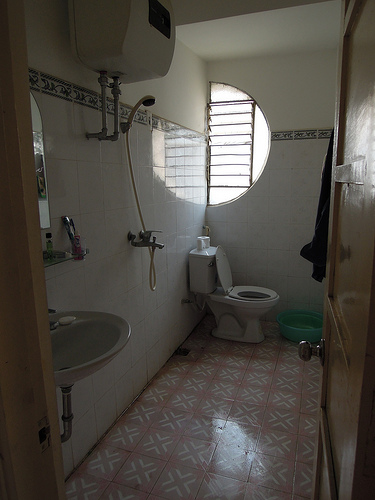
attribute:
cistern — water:
[182, 244, 220, 297]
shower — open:
[76, 5, 227, 404]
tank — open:
[192, 240, 274, 336]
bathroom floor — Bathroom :
[78, 345, 317, 498]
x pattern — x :
[234, 380, 269, 407]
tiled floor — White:
[65, 315, 321, 499]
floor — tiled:
[56, 340, 325, 496]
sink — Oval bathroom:
[73, 306, 127, 378]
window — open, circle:
[207, 81, 271, 207]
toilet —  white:
[184, 234, 279, 347]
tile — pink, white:
[235, 382, 271, 404]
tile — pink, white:
[262, 404, 299, 433]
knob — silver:
[296, 337, 324, 364]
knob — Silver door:
[296, 336, 327, 368]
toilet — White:
[191, 231, 285, 351]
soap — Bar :
[54, 314, 86, 333]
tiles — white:
[40, 105, 195, 338]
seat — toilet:
[228, 278, 277, 307]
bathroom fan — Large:
[64, 1, 178, 88]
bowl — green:
[281, 300, 317, 344]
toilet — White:
[201, 252, 272, 328]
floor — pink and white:
[174, 378, 279, 499]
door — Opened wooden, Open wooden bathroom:
[288, 0, 373, 498]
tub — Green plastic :
[280, 301, 326, 346]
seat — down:
[227, 282, 275, 312]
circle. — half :
[205, 77, 272, 202]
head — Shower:
[130, 93, 166, 118]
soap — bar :
[58, 306, 79, 321]